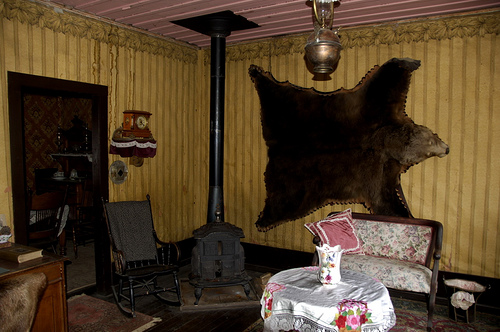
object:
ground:
[0, 233, 500, 331]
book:
[0, 242, 46, 264]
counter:
[0, 243, 74, 332]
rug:
[66, 291, 164, 332]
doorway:
[6, 69, 115, 299]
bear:
[248, 56, 451, 233]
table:
[256, 266, 395, 330]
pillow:
[300, 208, 364, 259]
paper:
[202, 11, 499, 281]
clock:
[120, 109, 153, 138]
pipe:
[204, 19, 231, 225]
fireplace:
[191, 221, 254, 306]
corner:
[176, 40, 226, 60]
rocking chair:
[97, 192, 183, 321]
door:
[22, 86, 96, 296]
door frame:
[6, 69, 113, 296]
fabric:
[339, 218, 431, 297]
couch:
[312, 210, 443, 332]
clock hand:
[141, 123, 146, 126]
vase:
[313, 242, 343, 286]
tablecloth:
[258, 265, 395, 332]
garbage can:
[441, 274, 492, 327]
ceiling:
[46, 1, 500, 49]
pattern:
[343, 218, 433, 266]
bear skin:
[247, 56, 448, 234]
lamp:
[301, 0, 343, 75]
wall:
[197, 12, 500, 308]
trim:
[334, 211, 441, 231]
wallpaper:
[0, 0, 206, 266]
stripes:
[479, 35, 500, 277]